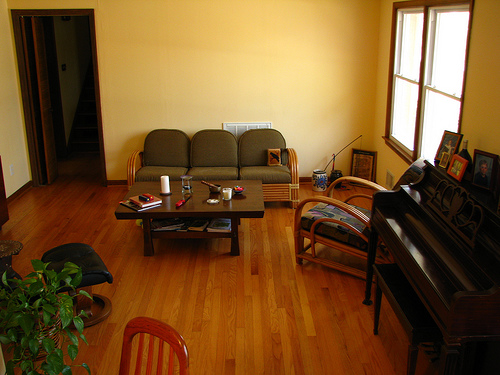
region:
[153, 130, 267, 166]
a couch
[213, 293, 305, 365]
the wooden floor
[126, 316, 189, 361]
a chair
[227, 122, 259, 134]
a white vent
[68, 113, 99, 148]
the stairs in the hall way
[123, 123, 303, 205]
brown couch with bamboo frame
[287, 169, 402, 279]
bamboo framed chair next to piano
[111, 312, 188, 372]
wooden chair back in foreground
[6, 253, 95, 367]
green plant in foreground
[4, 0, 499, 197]
painted yellow walls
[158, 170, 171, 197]
white candle on black table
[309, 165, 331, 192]
blue and white ceramic vase on floor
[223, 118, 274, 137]
white wall vent behind sofa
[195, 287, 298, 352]
floor made out of hardwood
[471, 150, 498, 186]
picture on top of piano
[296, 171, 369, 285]
chair sitting by the window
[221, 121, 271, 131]
vent on the wall behind the sofa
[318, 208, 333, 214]
cushion in the chair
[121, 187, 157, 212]
books sitting on the edge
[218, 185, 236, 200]
cup sitting on the table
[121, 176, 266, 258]
coffee table sitting in the middle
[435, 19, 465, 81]
Daylight coming from the window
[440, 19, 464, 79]
Sunshine coming from a window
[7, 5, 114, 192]
A doorway in a room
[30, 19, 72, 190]
The door is open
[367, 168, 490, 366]
A piano in a room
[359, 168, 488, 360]
The piano is made out of wood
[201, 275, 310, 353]
Hardwood floors in a room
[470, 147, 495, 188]
Picture in a frame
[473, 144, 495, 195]
Picture on a piano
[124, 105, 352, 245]
a couch that is green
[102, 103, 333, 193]
a green small couch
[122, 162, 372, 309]
a brown coffee table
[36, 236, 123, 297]
A black leather seat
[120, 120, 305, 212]
A couch is brown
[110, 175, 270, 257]
A wooden coffee table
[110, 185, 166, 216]
A stack of books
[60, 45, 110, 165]
A set of stairs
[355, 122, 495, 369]
A dark brown wooden piano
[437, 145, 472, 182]
A red photo frame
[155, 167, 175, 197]
A white wax candle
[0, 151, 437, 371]
A brown and wooden floor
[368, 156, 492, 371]
Brown piano in family room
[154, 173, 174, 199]
Tall white candle on the coffee table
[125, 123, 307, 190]
Brown couch against the wall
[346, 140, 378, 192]
Picture on the floor in the corner of the room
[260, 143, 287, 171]
Brown decorative pillow on the couch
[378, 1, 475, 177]
Large window with no blinds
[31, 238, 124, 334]
Blue footstool on the floor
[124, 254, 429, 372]
Clean brown hardwood floor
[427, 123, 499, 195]
Family pictures on top of the piano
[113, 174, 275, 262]
Brown coffee table in front of the couch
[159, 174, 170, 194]
Cylinder white candle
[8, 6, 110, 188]
Door with brown frame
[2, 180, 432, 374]
Brown hardwood floor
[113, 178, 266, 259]
Brown wooden coffee table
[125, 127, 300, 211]
Couch has green cushions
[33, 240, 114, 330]
Leather ottoman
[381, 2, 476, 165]
Wooden window has brown frame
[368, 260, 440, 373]
Dark brown piano bench